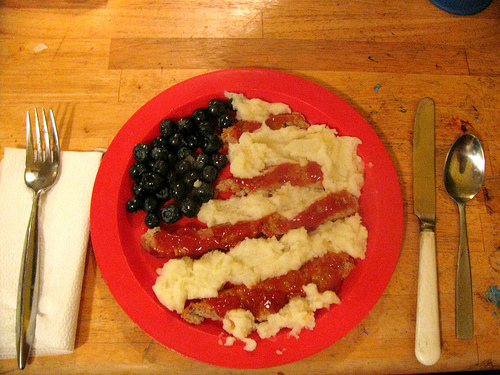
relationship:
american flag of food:
[124, 91, 361, 353] [125, 91, 366, 351]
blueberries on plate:
[124, 99, 231, 231] [87, 68, 403, 369]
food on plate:
[224, 91, 292, 123] [328, 87, 389, 182]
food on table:
[172, 125, 347, 306] [0, 0, 483, 369]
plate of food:
[87, 68, 403, 369] [172, 125, 347, 306]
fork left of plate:
[15, 107, 61, 365] [87, 68, 403, 369]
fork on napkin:
[15, 107, 61, 365] [2, 145, 102, 355]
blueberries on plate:
[121, 85, 242, 230] [87, 68, 403, 369]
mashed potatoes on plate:
[229, 121, 365, 197] [87, 68, 403, 369]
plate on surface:
[87, 68, 403, 369] [1, 1, 478, 367]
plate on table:
[87, 68, 403, 369] [0, 0, 483, 369]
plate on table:
[113, 68, 430, 345] [27, 14, 484, 346]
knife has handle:
[411, 97, 443, 367] [410, 223, 442, 362]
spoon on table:
[443, 132, 485, 339] [0, 0, 483, 369]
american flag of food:
[124, 91, 361, 353] [88, 44, 406, 359]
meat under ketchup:
[136, 191, 361, 246] [161, 226, 248, 242]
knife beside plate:
[411, 97, 443, 367] [87, 68, 403, 369]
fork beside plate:
[14, 107, 61, 368] [87, 68, 403, 369]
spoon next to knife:
[443, 132, 485, 339] [407, 89, 444, 372]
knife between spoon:
[411, 97, 444, 374] [442, 129, 482, 343]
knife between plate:
[411, 97, 444, 374] [87, 68, 403, 369]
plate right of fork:
[87, 68, 403, 369] [15, 107, 61, 365]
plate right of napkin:
[87, 68, 403, 369] [0, 140, 111, 363]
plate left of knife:
[87, 68, 403, 369] [399, 73, 456, 367]